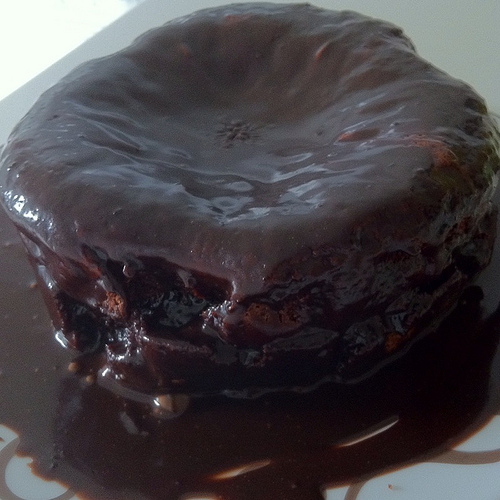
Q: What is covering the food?
A: Chocolate.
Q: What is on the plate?
A: Chocolate and some sauce.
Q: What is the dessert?
A: Chocolate cake.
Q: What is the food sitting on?
A: A plate.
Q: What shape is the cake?
A: Round.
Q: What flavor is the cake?
A: Chocolate.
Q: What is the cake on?
A: Plate.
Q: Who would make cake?
A: Baker.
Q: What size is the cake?
A: Small.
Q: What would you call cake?
A: Desert.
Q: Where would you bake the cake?
A: Oven.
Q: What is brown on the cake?
A: Frosting.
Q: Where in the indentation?
A: On top of cake.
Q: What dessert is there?
A: Chocolate cake.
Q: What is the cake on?
A: Plate.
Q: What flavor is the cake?
A: Chocolate.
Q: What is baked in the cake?
A: Nuts.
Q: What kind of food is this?
A: Dessert.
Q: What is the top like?
A: Caved in.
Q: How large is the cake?
A: Small.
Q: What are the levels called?
A: Layers.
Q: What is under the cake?
A: Sauce.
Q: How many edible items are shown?
A: One.